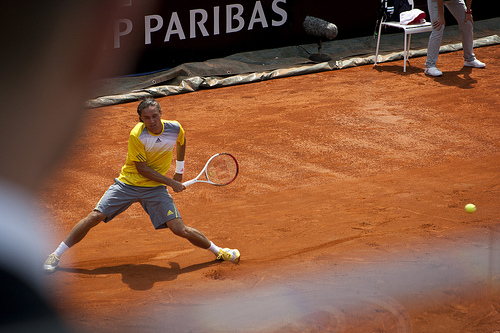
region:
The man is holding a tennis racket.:
[39, 88, 263, 277]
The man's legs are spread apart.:
[41, 91, 250, 283]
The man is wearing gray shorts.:
[37, 88, 252, 286]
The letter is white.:
[137, 7, 166, 51]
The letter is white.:
[159, 8, 186, 50]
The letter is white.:
[184, 2, 213, 43]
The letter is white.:
[211, 0, 225, 46]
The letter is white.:
[220, 1, 249, 41]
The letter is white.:
[243, 0, 273, 37]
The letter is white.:
[267, 0, 292, 34]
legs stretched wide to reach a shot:
[45, 186, 239, 270]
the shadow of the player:
[57, 255, 225, 291]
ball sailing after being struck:
[461, 201, 484, 214]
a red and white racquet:
[183, 151, 240, 187]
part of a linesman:
[419, 0, 485, 87]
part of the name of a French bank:
[136, 0, 289, 46]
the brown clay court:
[44, 44, 498, 331]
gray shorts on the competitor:
[94, 181, 181, 229]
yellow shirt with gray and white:
[117, 117, 188, 187]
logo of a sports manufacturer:
[212, 155, 231, 185]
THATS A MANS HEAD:
[131, 95, 166, 135]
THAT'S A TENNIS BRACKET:
[178, 150, 239, 187]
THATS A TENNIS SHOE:
[219, 245, 241, 265]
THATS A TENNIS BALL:
[462, 201, 477, 215]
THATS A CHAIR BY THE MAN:
[373, 1, 431, 73]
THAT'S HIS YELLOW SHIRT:
[116, 120, 187, 188]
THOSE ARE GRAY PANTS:
[424, 0, 476, 67]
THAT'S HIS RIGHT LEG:
[48, 192, 123, 252]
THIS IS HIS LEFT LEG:
[157, 204, 224, 249]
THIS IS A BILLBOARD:
[142, 0, 296, 50]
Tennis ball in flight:
[458, 200, 477, 217]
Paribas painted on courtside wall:
[145, 2, 287, 48]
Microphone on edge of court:
[300, 13, 340, 64]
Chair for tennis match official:
[365, 0, 430, 70]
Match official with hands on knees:
[422, 1, 488, 80]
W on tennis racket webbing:
[212, 156, 231, 183]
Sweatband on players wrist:
[173, 159, 185, 176]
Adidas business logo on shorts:
[162, 209, 177, 218]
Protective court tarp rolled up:
[79, 15, 499, 112]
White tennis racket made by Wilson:
[176, 151, 241, 190]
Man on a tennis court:
[68, 95, 271, 300]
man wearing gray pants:
[88, 163, 197, 227]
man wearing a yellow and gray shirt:
[119, 115, 204, 199]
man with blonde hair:
[126, 92, 174, 137]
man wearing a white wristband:
[168, 154, 191, 176]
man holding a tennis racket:
[164, 155, 254, 201]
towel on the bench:
[393, 0, 430, 29]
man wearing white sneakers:
[422, 63, 444, 78]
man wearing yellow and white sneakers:
[208, 224, 245, 274]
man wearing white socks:
[203, 228, 226, 257]